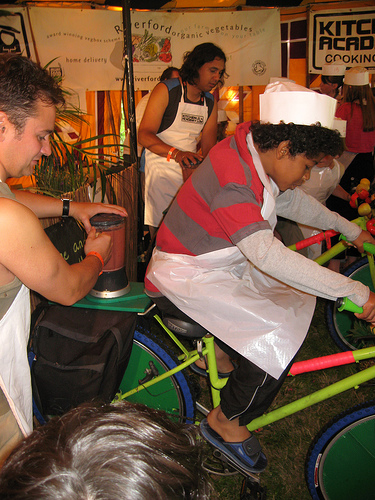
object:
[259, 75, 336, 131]
hat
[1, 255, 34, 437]
apron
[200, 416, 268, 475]
sandal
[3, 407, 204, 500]
head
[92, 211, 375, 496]
bike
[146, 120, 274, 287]
shirt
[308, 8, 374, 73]
sign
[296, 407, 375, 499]
wheel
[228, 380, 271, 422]
stripe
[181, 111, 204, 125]
logo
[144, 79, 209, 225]
apron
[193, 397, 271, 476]
foot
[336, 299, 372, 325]
handlebar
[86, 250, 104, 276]
wrist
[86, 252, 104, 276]
bracelet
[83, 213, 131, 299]
blender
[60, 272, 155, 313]
table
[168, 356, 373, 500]
grass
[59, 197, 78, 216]
watch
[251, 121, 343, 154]
hair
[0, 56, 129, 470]
man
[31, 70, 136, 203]
leaves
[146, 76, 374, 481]
girl